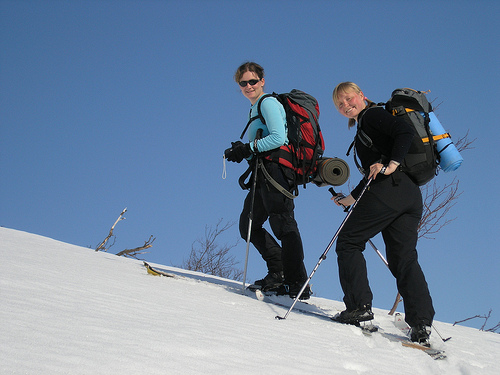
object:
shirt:
[240, 93, 290, 161]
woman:
[319, 76, 434, 348]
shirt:
[355, 102, 410, 170]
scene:
[0, 0, 500, 375]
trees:
[386, 97, 478, 317]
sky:
[2, 1, 500, 325]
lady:
[331, 80, 436, 345]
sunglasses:
[239, 79, 261, 87]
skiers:
[223, 62, 310, 299]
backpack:
[248, 88, 325, 184]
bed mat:
[420, 112, 462, 173]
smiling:
[240, 86, 259, 96]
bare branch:
[179, 215, 244, 281]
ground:
[0, 228, 500, 375]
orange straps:
[422, 133, 451, 143]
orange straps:
[392, 108, 412, 116]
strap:
[379, 166, 386, 174]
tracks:
[332, 313, 446, 362]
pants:
[238, 160, 308, 283]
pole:
[273, 174, 375, 320]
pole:
[327, 187, 453, 344]